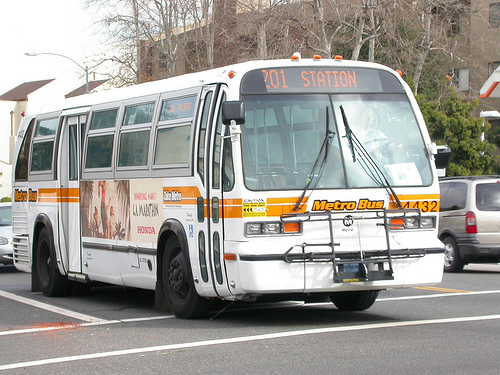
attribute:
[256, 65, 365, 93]
sign — 201 station, orange, led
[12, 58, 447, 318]
bus — white, driving, orange, metro bus, 4432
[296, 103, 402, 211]
windshield wipers — black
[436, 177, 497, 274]
van — grey, gray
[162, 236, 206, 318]
tire — black, large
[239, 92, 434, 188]
windshield — glass, large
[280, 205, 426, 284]
bike rack — silver, black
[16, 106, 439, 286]
bus frame — white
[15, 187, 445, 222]
stripe — orange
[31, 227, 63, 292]
wheel — black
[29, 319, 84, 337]
spill — red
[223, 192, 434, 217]
lines — white, orange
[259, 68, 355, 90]
writing — orange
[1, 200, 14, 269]
car — silver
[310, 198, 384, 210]
logo — black, small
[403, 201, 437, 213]
numbering — black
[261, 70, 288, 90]
number — 201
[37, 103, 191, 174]
windows — side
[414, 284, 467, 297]
line — yellow